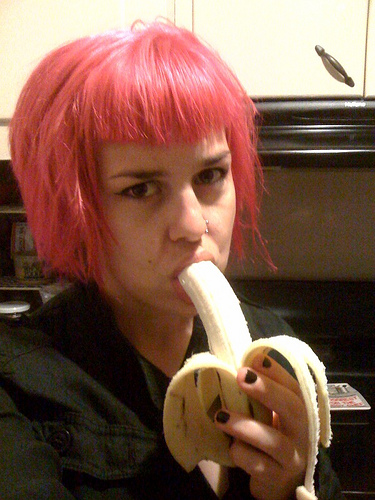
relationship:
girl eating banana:
[0, 4, 344, 500] [167, 250, 340, 498]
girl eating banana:
[0, 4, 344, 500] [154, 250, 333, 493]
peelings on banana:
[240, 332, 344, 498] [177, 248, 280, 463]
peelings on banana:
[159, 344, 265, 476] [177, 248, 280, 463]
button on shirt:
[44, 428, 76, 462] [1, 273, 355, 498]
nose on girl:
[164, 175, 213, 250] [0, 4, 344, 500]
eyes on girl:
[114, 171, 167, 205] [0, 4, 344, 500]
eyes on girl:
[191, 161, 229, 189] [0, 4, 344, 500]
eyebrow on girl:
[105, 160, 164, 181] [0, 4, 344, 500]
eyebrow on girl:
[196, 146, 234, 165] [0, 4, 344, 500]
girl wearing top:
[0, 4, 344, 500] [1, 265, 346, 497]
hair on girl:
[9, 16, 288, 292] [0, 4, 344, 500]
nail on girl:
[242, 366, 266, 392] [0, 4, 344, 500]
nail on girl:
[213, 411, 235, 427] [0, 4, 344, 500]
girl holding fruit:
[0, 4, 344, 500] [166, 257, 333, 492]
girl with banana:
[31, 65, 282, 418] [166, 252, 264, 377]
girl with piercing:
[0, 4, 344, 500] [189, 209, 214, 229]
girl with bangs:
[0, 4, 344, 500] [86, 83, 216, 161]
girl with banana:
[31, 65, 282, 418] [170, 262, 296, 391]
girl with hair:
[0, 4, 344, 500] [32, 40, 237, 224]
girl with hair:
[0, 4, 344, 500] [41, 38, 274, 168]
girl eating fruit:
[0, 4, 344, 500] [166, 257, 333, 492]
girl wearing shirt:
[0, 4, 344, 500] [6, 288, 276, 492]